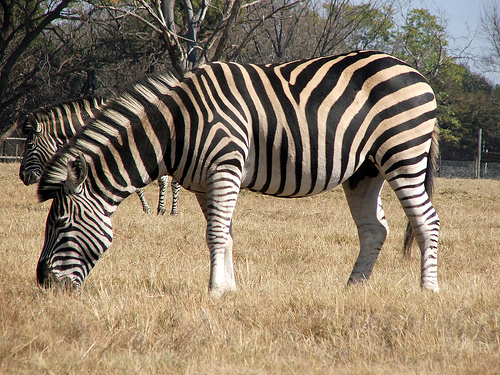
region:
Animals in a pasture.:
[5, 46, 496, 368]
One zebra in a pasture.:
[32, 48, 453, 301]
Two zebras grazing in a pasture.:
[13, 46, 458, 310]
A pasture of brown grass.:
[3, 165, 498, 371]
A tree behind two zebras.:
[100, 0, 300, 220]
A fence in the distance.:
[2, 133, 30, 167]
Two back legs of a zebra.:
[322, 139, 456, 300]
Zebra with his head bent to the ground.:
[31, 49, 462, 309]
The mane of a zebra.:
[28, 63, 190, 200]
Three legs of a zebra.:
[122, 174, 185, 220]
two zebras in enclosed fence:
[6, 48, 498, 335]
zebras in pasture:
[21, 45, 456, 320]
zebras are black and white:
[13, 118, 468, 327]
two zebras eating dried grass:
[21, 27, 466, 326]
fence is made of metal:
[441, 153, 498, 182]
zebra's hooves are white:
[211, 265, 249, 304]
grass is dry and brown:
[3, 180, 498, 364]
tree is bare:
[116, 6, 321, 71]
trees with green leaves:
[403, 6, 498, 157]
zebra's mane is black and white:
[37, 54, 176, 197]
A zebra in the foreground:
[32, 42, 454, 314]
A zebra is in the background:
[8, 93, 129, 192]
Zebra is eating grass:
[30, 160, 126, 300]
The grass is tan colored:
[0, 165, 497, 374]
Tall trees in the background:
[3, 0, 498, 155]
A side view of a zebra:
[26, 44, 451, 312]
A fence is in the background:
[0, 128, 499, 187]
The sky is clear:
[349, 3, 499, 88]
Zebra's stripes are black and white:
[29, 45, 461, 304]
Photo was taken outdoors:
[3, 8, 496, 366]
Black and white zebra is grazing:
[31, 52, 443, 296]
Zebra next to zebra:
[15, 93, 181, 217]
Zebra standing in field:
[33, 46, 447, 298]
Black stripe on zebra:
[304, 49, 386, 204]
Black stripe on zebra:
[255, 61, 303, 197]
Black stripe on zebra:
[240, 60, 276, 195]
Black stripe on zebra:
[223, 59, 261, 189]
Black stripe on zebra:
[142, 100, 176, 177]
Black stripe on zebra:
[337, 71, 426, 196]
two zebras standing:
[0, 39, 449, 308]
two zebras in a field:
[8, 57, 442, 317]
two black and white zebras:
[2, 42, 453, 324]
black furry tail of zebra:
[417, 135, 434, 217]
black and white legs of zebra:
[195, 163, 454, 305]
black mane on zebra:
[100, 62, 165, 114]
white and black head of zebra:
[23, 146, 117, 294]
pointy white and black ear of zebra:
[68, 143, 90, 200]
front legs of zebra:
[185, 196, 239, 297]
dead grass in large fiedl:
[34, 293, 234, 371]